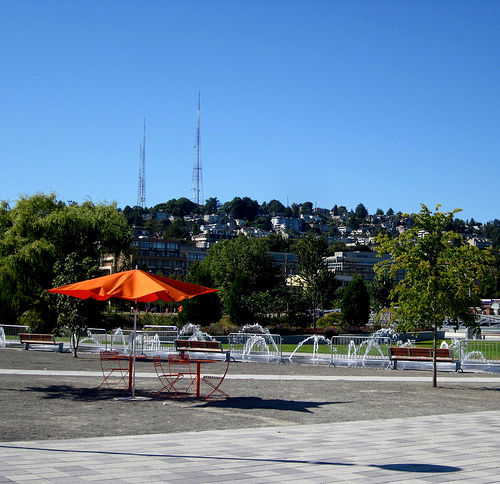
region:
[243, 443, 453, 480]
shadow is on the ground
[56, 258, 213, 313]
the umbrella is orange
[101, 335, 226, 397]
the chairs are orange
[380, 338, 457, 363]
the bench is wooden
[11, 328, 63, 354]
the bench is wooden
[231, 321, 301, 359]
water is splashing in the air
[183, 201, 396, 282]
the hilltop has houses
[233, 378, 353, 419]
umbrella shadow is on the ground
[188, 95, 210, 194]
the tower is tall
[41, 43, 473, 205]
the sky is cloudless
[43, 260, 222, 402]
an orange outdoor shade umbrella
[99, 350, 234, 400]
an orange table and chairs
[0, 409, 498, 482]
a walkway made of pavers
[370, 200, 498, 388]
a tree with green leaves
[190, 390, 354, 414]
a shadow from the table,chairs, and umbrella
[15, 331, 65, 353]
a brown bench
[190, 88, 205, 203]
a cellphone utility tower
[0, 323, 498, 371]
fountains in a park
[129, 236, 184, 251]
a row of windows in a building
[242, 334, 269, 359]
a spout of water from the fountain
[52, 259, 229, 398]
orange umbrella shading table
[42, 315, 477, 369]
water feature in distance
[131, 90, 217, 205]
two antennas on hill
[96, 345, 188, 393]
chairs sitting underneath umbrella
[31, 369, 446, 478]
shadows on the cement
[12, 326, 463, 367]
benches in front of water feature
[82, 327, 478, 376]
water spouts shooting water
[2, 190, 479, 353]
trees around water feature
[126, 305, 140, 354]
pole of orange umbrellas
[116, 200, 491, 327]
houses and building in distance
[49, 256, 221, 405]
large bright orange umbrella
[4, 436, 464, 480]
shadow from a sign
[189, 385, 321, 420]
shadow on the ground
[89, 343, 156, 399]
chair pushed into a table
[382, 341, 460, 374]
brown bench on the concrete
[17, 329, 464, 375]
row of three benches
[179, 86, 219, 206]
tall pole towering over the tree tops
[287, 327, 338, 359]
stream of water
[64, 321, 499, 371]
various streams of water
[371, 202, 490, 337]
dark green tre top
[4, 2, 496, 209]
clear blue of daytime sky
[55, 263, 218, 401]
orange umbrella on stand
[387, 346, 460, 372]
back of park bench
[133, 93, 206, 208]
two towers on horizon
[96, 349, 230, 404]
orange chairs and tables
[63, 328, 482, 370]
spouting water of fountains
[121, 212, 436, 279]
buildings on side of hill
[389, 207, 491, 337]
green leaves on tree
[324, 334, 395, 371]
metal gate in front of fountain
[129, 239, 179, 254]
window on side of building